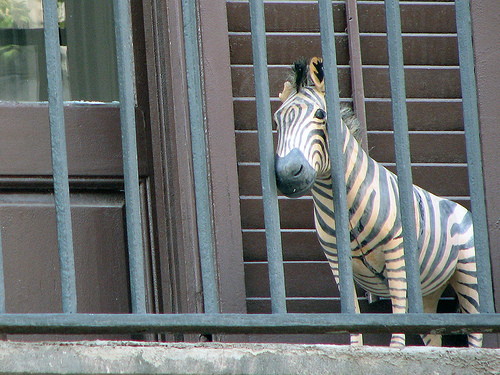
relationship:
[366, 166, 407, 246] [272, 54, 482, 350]
stripe on zebra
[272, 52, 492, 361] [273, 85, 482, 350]
zebra with stripes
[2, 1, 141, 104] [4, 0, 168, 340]
window in door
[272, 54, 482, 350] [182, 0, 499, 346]
zebra in cage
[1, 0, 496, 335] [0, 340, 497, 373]
fence of balcony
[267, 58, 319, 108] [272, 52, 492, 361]
mane on zebra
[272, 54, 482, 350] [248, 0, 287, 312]
zebra behind bar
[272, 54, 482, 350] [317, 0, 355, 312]
zebra behind bar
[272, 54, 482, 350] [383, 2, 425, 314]
zebra behind bar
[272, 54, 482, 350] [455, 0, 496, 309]
zebra behind bar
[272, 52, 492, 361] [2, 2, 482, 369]
zebra standing outside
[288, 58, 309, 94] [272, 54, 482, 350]
mane belonging to zebra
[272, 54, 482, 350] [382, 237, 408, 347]
zebra with leg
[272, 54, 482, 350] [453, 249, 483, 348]
zebra with leg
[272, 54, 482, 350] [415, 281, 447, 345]
zebra with leg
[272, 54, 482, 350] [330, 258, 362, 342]
zebra with leg